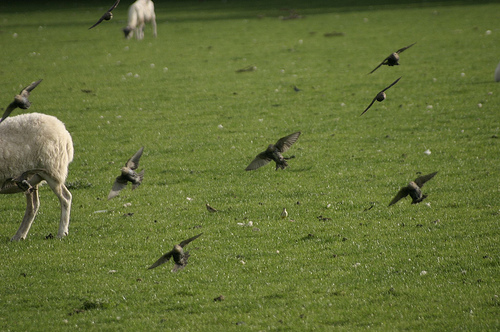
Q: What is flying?
A: Birds.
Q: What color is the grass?
A: Green.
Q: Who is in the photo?
A: Nobody.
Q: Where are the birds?
A: In the air.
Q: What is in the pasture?
A: Sheep.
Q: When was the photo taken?
A: Daytime.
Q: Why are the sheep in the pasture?
A: To graze.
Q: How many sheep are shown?
A: Two.